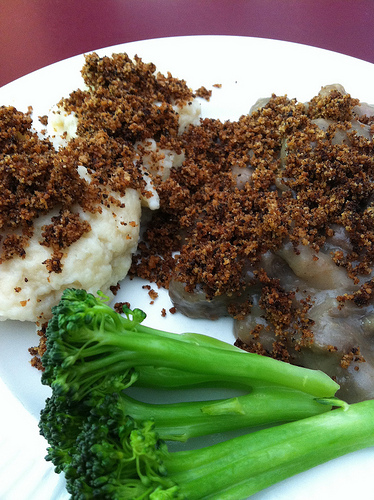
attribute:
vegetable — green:
[28, 283, 370, 492]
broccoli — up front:
[35, 284, 372, 498]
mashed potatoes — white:
[0, 96, 200, 323]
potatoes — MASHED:
[86, 250, 99, 269]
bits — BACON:
[332, 352, 352, 366]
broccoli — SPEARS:
[5, 293, 362, 473]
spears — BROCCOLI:
[174, 355, 299, 486]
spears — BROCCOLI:
[216, 327, 362, 468]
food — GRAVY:
[220, 110, 331, 308]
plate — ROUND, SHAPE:
[7, 361, 22, 403]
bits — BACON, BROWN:
[271, 303, 285, 319]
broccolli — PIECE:
[124, 298, 155, 327]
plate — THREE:
[324, 475, 349, 489]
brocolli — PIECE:
[47, 299, 342, 462]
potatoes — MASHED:
[95, 240, 111, 266]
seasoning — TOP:
[280, 184, 340, 207]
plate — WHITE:
[10, 335, 21, 381]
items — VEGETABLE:
[50, 303, 318, 485]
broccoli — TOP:
[52, 311, 339, 474]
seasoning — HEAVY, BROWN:
[209, 126, 313, 206]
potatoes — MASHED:
[83, 244, 100, 267]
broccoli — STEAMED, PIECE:
[55, 315, 358, 498]